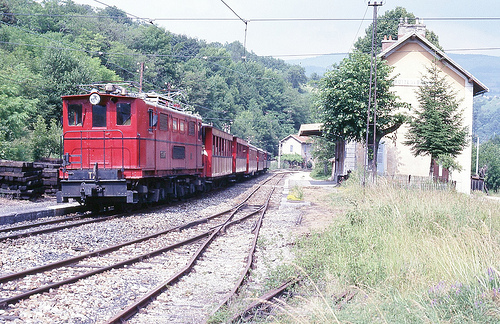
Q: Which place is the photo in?
A: It is at the railroad.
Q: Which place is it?
A: It is a railroad.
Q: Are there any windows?
A: Yes, there is a window.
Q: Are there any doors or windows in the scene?
A: Yes, there is a window.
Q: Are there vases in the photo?
A: No, there are no vases.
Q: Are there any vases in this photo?
A: No, there are no vases.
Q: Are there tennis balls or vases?
A: No, there are no vases or tennis balls.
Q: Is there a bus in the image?
A: No, there are no buses.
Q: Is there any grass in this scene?
A: Yes, there is grass.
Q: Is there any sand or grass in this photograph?
A: Yes, there is grass.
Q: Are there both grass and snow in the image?
A: No, there is grass but no snow.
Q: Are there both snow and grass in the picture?
A: No, there is grass but no snow.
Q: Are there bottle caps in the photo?
A: No, there are no bottle caps.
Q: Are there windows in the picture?
A: Yes, there is a window.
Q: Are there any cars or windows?
A: Yes, there is a window.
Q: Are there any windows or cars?
A: Yes, there is a window.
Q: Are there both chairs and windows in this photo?
A: No, there is a window but no chairs.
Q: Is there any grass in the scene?
A: Yes, there is grass.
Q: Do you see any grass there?
A: Yes, there is grass.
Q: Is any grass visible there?
A: Yes, there is grass.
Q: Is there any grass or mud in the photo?
A: Yes, there is grass.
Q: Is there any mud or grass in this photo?
A: Yes, there is grass.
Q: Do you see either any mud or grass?
A: Yes, there is grass.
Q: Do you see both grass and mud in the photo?
A: No, there is grass but no mud.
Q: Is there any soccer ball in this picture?
A: No, there are no soccer balls.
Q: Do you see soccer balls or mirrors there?
A: No, there are no soccer balls or mirrors.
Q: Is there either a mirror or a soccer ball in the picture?
A: No, there are no soccer balls or mirrors.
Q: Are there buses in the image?
A: No, there are no buses.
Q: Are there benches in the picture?
A: No, there are no benches.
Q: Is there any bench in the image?
A: No, there are no benches.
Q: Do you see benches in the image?
A: No, there are no benches.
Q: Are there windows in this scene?
A: Yes, there is a window.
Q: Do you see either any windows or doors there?
A: Yes, there is a window.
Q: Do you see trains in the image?
A: Yes, there is a train.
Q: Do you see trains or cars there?
A: Yes, there is a train.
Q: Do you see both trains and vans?
A: No, there is a train but no vans.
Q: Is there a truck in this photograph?
A: No, there are no trucks.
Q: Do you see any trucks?
A: No, there are no trucks.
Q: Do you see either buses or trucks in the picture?
A: No, there are no trucks or buses.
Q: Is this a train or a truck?
A: This is a train.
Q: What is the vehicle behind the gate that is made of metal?
A: The vehicle is a train.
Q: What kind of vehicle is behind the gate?
A: The vehicle is a train.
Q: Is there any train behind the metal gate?
A: Yes, there is a train behind the gate.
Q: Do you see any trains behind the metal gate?
A: Yes, there is a train behind the gate.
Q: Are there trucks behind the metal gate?
A: No, there is a train behind the gate.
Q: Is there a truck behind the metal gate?
A: No, there is a train behind the gate.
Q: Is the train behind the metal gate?
A: Yes, the train is behind the gate.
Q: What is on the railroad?
A: The train is on the railroad.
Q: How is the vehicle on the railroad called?
A: The vehicle is a train.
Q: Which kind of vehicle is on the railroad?
A: The vehicle is a train.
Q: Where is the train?
A: The train is on the railroad.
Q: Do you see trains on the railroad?
A: Yes, there is a train on the railroad.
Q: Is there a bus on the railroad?
A: No, there is a train on the railroad.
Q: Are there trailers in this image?
A: No, there are no trailers.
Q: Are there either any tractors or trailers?
A: No, there are no trailers or tractors.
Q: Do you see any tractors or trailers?
A: No, there are no trailers or tractors.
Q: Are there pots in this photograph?
A: No, there are no pots.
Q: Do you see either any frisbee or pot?
A: No, there are no pots or frisbees.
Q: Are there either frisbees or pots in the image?
A: No, there are no pots or frisbees.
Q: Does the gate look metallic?
A: Yes, the gate is metallic.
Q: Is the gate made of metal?
A: Yes, the gate is made of metal.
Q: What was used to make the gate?
A: The gate is made of metal.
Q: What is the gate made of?
A: The gate is made of metal.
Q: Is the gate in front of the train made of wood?
A: No, the gate is made of metal.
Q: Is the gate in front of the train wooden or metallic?
A: The gate is metallic.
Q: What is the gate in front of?
A: The gate is in front of the train.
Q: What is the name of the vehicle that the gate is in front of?
A: The vehicle is a train.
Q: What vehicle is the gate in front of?
A: The gate is in front of the train.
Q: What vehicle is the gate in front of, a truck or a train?
A: The gate is in front of a train.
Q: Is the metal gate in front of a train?
A: Yes, the gate is in front of a train.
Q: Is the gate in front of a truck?
A: No, the gate is in front of a train.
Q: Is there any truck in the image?
A: No, there are no trucks.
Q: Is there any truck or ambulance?
A: No, there are no trucks or ambulances.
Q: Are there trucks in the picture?
A: No, there are no trucks.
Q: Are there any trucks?
A: No, there are no trucks.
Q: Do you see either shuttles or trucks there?
A: No, there are no trucks or shuttles.